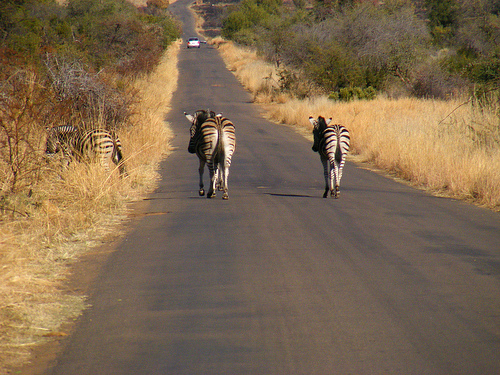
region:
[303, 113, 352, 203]
zebra walking on the right side of the road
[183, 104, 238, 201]
zebra walking on the left side of the road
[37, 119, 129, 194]
zebra walking into the brown grass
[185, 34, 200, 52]
car in the middle of the road well in front of zebras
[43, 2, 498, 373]
road that the zebras and the car are on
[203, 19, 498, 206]
brown grass on the right side of the road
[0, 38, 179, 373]
brown grass on the left side of the road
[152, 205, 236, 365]
dark spot in the road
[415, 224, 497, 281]
dark spot in the road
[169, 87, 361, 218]
two zebras in the road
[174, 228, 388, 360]
black concrete road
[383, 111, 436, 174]
tall brown grass on the side of the road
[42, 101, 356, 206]
three zebras walking outside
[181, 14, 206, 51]
white car in the middle of the road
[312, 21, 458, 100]
green trees on the side of the road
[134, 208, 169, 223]
brown circular hole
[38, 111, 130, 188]
zebra eating brown grass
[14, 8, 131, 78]
green and orange trees on the side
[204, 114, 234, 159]
zebra's rear end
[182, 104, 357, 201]
Two zebreas walking down the road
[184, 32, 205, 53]
Car ahead of them in the distance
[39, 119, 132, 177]
Third zebra off to the side of the road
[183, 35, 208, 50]
Red tail lights on the car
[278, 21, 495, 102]
Bush overgrowth ahead of the zebras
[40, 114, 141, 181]
Third zebra is feeding off to the side of the road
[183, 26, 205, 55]
The car is silver in color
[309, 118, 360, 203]
Zebra is black and white in color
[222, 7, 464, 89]
Small trees on down the road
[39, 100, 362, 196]
zebras in road and field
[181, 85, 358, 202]
zebras in road area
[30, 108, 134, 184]
zebra in grass area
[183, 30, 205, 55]
vehicle on the road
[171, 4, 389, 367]
road with vehicles and zebras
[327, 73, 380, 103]
bushes growing among plants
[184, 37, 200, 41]
window to a vehicle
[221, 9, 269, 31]
trees in the distance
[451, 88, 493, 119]
twigs and branches from trees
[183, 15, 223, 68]
this is a car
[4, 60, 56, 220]
this is a shrub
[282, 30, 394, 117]
this is a shrub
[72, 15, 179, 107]
this is a shrub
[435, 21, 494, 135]
this is a shrub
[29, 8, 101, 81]
this is a shrub